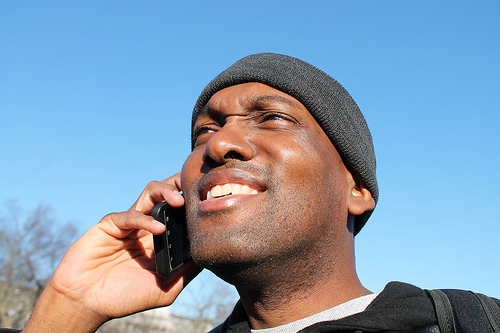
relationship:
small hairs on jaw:
[174, 163, 336, 309] [227, 210, 336, 272]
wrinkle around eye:
[276, 121, 298, 130] [251, 102, 304, 141]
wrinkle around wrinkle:
[261, 124, 283, 130] [276, 121, 298, 130]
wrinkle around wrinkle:
[245, 112, 257, 126] [276, 121, 298, 130]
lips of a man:
[196, 167, 268, 212] [17, 52, 498, 332]